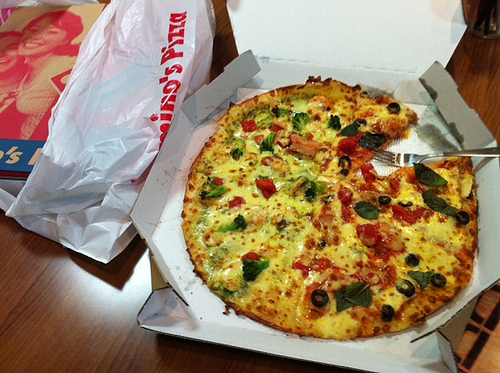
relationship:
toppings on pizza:
[274, 229, 406, 317] [191, 85, 472, 326]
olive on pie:
[304, 173, 324, 196] [182, 76, 482, 336]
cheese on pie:
[273, 239, 305, 266] [184, 80, 466, 317]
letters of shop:
[155, 9, 183, 155] [7, 9, 484, 353]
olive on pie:
[305, 285, 332, 315] [182, 76, 479, 341]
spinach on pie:
[326, 275, 376, 320] [182, 76, 479, 341]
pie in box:
[182, 76, 479, 341] [122, 4, 498, 372]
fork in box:
[373, 147, 500, 168] [122, 4, 498, 372]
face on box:
[15, 16, 69, 64] [4, 5, 104, 176]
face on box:
[4, 32, 28, 80] [4, 1, 118, 176]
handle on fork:
[427, 143, 497, 163] [367, 143, 497, 170]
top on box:
[225, 1, 475, 102] [122, 4, 498, 372]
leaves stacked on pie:
[329, 274, 380, 318] [182, 76, 479, 341]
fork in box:
[365, 140, 498, 168] [122, 4, 498, 372]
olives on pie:
[305, 285, 336, 312] [182, 76, 479, 341]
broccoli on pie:
[234, 249, 274, 287] [182, 76, 479, 341]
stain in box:
[411, 119, 461, 159] [122, 4, 498, 372]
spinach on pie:
[328, 279, 380, 315] [182, 76, 479, 341]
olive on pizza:
[280, 280, 339, 317] [178, 53, 477, 343]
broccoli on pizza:
[253, 125, 289, 175] [178, 53, 477, 343]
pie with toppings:
[182, 76, 479, 341] [205, 111, 491, 314]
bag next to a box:
[51, 21, 171, 265] [6, 20, 176, 210]